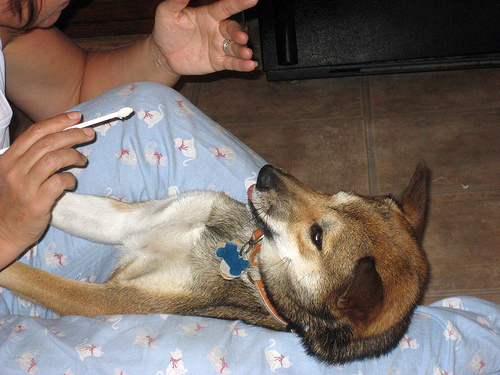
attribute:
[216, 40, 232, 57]
ring — Silver 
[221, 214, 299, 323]
collar — orange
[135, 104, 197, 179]
cats — pattern 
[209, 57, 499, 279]
patterns — square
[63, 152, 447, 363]
dog — brown, white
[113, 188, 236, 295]
chest — white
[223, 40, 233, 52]
ring — silver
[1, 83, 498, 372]
pants — light blue, long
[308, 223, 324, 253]
eye — black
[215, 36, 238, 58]
ring — silver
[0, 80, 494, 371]
pajamas — blue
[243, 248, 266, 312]
collar — Leather 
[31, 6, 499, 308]
floor — wood